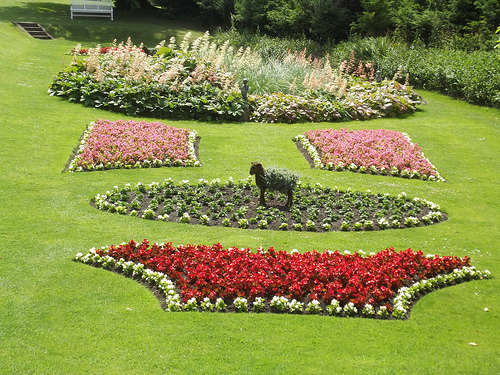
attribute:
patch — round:
[89, 174, 449, 234]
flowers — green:
[93, 179, 444, 232]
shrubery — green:
[338, 16, 496, 101]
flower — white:
[291, 297, 301, 315]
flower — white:
[303, 296, 323, 315]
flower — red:
[105, 243, 465, 314]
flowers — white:
[42, 23, 427, 144]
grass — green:
[43, 89, 410, 354]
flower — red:
[303, 283, 316, 296]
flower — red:
[371, 280, 387, 295]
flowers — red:
[184, 263, 213, 285]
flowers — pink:
[69, 118, 200, 170]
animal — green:
[242, 155, 314, 210]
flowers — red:
[180, 256, 393, 296]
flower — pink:
[339, 149, 353, 161]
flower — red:
[185, 287, 204, 297]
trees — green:
[397, 6, 424, 54]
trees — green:
[449, 2, 488, 39]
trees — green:
[302, 2, 346, 52]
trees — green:
[264, 1, 301, 44]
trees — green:
[223, 0, 259, 42]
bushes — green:
[350, 35, 385, 77]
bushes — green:
[437, 62, 467, 106]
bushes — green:
[376, 52, 399, 89]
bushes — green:
[477, 72, 499, 97]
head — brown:
[247, 160, 267, 179]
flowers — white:
[163, 291, 410, 321]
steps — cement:
[18, 18, 54, 42]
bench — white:
[63, 1, 119, 25]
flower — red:
[92, 248, 107, 257]